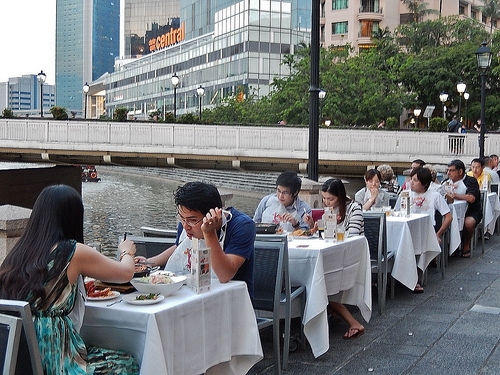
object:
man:
[132, 179, 257, 308]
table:
[71, 267, 267, 374]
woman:
[0, 182, 141, 374]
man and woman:
[1, 180, 258, 375]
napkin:
[159, 204, 235, 280]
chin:
[185, 236, 203, 243]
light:
[473, 33, 500, 174]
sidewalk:
[287, 215, 500, 373]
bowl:
[127, 273, 188, 298]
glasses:
[173, 211, 208, 228]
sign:
[145, 22, 190, 53]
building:
[102, 0, 310, 121]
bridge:
[0, 115, 499, 181]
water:
[79, 174, 268, 261]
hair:
[0, 183, 85, 323]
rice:
[135, 271, 177, 287]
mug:
[334, 227, 346, 244]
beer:
[335, 232, 345, 243]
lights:
[168, 73, 184, 121]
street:
[292, 240, 498, 374]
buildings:
[53, 0, 121, 119]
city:
[0, 2, 499, 370]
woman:
[310, 171, 377, 350]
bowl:
[122, 291, 167, 305]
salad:
[131, 289, 160, 303]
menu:
[322, 212, 339, 240]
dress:
[6, 236, 143, 374]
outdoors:
[0, 151, 500, 368]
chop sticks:
[123, 233, 127, 242]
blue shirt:
[174, 207, 256, 294]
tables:
[358, 207, 443, 292]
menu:
[183, 246, 214, 294]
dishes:
[120, 291, 168, 305]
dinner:
[83, 249, 244, 311]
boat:
[81, 165, 103, 184]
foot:
[343, 320, 368, 341]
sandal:
[341, 325, 368, 342]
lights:
[437, 89, 449, 131]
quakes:
[81, 173, 174, 224]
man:
[252, 171, 314, 232]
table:
[254, 224, 373, 359]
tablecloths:
[81, 263, 266, 374]